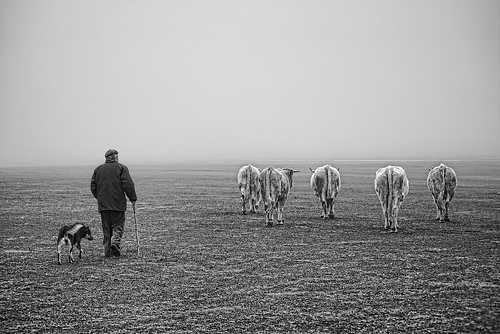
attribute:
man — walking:
[76, 147, 143, 257]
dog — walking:
[47, 226, 96, 264]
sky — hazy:
[4, 3, 490, 159]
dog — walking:
[43, 198, 110, 275]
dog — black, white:
[56, 220, 95, 264]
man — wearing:
[89, 149, 136, 256]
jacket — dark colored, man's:
[89, 160, 137, 212]